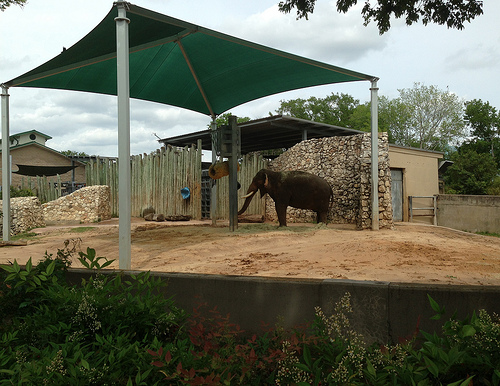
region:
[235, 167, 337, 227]
a brown elephant standing under a tent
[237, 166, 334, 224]
a brown elephant at the zoo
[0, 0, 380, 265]
a green canopy on metal poles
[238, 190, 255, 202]
a tusk on the left side of the elephant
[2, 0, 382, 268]
a green canopy supported by silver metal poles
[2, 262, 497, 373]
a brick wall surrounding the elephant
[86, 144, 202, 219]
a wooden fence separating the elephant and a small building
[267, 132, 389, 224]
a stone wall beside an elephant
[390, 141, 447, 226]
the side of a small building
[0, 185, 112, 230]
two large stones on the side of the canopy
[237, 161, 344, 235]
The elephant is turned to the left.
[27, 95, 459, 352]
The elephant is in a zoo.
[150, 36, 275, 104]
The color of the awning is green.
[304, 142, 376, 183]
The wall is a stone wall.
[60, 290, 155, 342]
The bush leaves are green.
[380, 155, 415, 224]
The elephant sometimes goes in the door.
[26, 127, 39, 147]
The window is circular in size.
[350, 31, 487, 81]
The sky is partly cloudy.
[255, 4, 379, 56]
The clouds are white and grey.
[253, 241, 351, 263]
The ground is sand.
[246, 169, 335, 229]
Small elephant standing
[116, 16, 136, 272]
Long grey metal pole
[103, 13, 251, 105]
Large green canopy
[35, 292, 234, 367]
Large amount of uncut shrubs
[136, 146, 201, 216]
Tall brown wooden fence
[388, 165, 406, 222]
Solid grey door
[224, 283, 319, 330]
Long grey concrete wall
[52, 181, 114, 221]
Slanted mixed stone wall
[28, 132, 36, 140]
Small window on gable of roof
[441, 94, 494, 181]
group of trees in background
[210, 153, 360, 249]
An elephant is under a tent.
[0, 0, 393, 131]
The tent is green.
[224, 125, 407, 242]
A wall is behind the elephant.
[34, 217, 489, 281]
The ground is covered with dirt.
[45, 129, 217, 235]
A fence is under the tent.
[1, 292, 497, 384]
Plants are in front of the elephant enclosure.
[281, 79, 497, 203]
Trees are behind the enclosure.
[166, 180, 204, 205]
A blue bucket is on the fence.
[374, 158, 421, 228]
The building has a door.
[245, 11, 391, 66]
Clouds are in the sky.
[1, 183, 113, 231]
two low stone walls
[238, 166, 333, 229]
elephant standing in enclosure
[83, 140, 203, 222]
fencing of uneven tree limbs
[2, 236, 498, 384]
planter area with decorative shrubbery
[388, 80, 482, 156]
tree with white leaves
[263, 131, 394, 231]
tall stone fence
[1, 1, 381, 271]
high canvas shading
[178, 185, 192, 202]
blue bucket hung on fence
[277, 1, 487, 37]
overhanging tree branches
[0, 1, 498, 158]
sky filled with low clouds